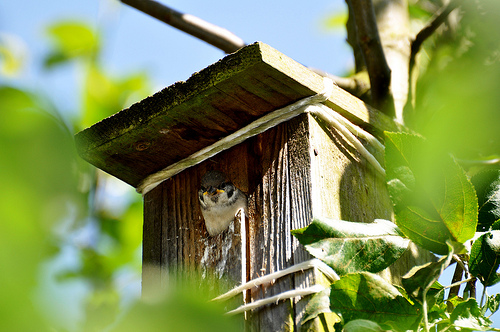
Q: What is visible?
A: A tree.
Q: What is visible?
A: Leaves.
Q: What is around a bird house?
A: Twine.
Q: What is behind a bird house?
A: Tree trunk.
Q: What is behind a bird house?
A: Tree limb.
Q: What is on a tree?
A: Leaves.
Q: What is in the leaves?
A: A birdhouse.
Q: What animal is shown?
A: A bird.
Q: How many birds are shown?
A: One.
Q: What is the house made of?
A: Wood.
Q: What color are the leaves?
A: Green.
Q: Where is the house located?
A: In tree.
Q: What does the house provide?
A: Shelter.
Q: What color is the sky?
A: Blue.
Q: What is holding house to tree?
A: White cord.